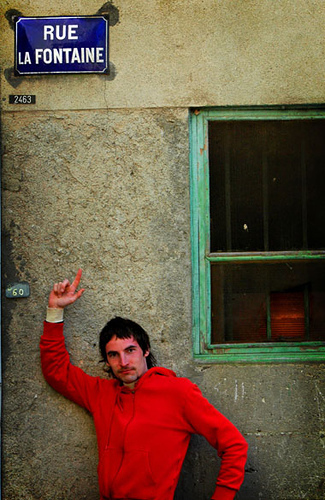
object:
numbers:
[27, 93, 33, 102]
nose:
[116, 352, 128, 368]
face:
[102, 333, 145, 382]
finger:
[68, 265, 85, 291]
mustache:
[116, 365, 134, 377]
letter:
[41, 23, 57, 43]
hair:
[97, 314, 157, 381]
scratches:
[225, 374, 247, 410]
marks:
[234, 377, 245, 407]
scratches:
[261, 432, 322, 499]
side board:
[187, 108, 213, 357]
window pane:
[211, 263, 325, 349]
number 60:
[11, 283, 25, 298]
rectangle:
[6, 91, 39, 106]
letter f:
[34, 48, 45, 67]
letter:
[55, 24, 66, 41]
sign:
[12, 12, 111, 82]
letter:
[17, 50, 23, 65]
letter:
[23, 51, 32, 63]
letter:
[43, 48, 53, 66]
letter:
[52, 46, 64, 63]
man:
[38, 267, 250, 499]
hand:
[47, 265, 86, 306]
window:
[205, 114, 325, 253]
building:
[1, 1, 325, 499]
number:
[11, 287, 18, 296]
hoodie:
[38, 319, 249, 499]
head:
[98, 314, 150, 388]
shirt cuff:
[44, 306, 67, 324]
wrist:
[45, 304, 65, 323]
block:
[4, 282, 30, 306]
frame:
[189, 105, 325, 369]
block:
[7, 90, 35, 103]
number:
[13, 94, 17, 105]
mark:
[240, 219, 249, 232]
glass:
[207, 117, 325, 260]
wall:
[0, 1, 325, 499]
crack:
[314, 383, 325, 420]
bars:
[203, 116, 325, 345]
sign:
[9, 93, 35, 107]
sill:
[193, 340, 325, 367]